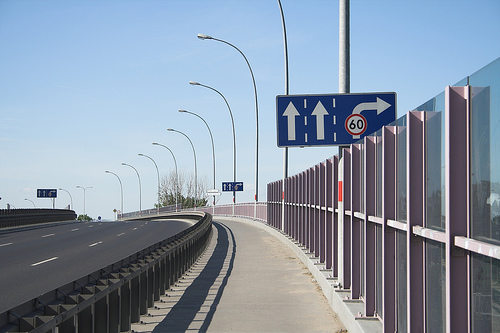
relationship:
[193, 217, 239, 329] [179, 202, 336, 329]
shadow on cement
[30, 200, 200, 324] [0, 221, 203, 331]
guard rail on freeway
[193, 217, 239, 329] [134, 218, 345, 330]
shadow on sidewalk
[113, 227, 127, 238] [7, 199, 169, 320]
white line in street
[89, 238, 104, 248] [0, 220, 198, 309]
white line on street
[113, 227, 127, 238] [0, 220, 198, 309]
white line on street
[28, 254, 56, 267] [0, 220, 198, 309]
white line on street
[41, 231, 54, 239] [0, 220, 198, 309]
white line on street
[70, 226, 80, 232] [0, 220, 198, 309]
white line on street